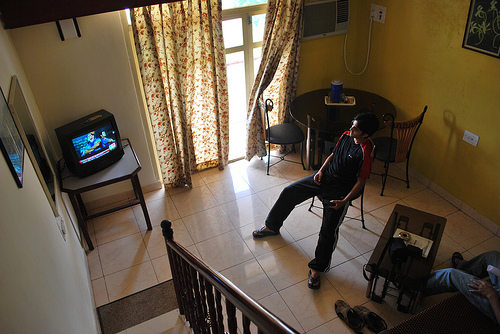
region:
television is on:
[49, 103, 140, 185]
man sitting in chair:
[247, 97, 386, 303]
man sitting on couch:
[403, 215, 498, 327]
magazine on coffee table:
[391, 215, 438, 262]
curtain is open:
[221, 0, 308, 167]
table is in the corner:
[278, 65, 421, 182]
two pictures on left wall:
[0, 52, 67, 245]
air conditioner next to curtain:
[300, 0, 401, 82]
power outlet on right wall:
[452, 115, 492, 160]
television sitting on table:
[50, 96, 170, 253]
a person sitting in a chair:
[240, 78, 425, 278]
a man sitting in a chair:
[257, 75, 407, 292]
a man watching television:
[19, 60, 436, 264]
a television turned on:
[54, 80, 171, 220]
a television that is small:
[39, 74, 153, 185]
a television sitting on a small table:
[50, 85, 182, 264]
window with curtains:
[118, 7, 400, 182]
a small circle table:
[232, 47, 444, 188]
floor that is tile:
[157, 188, 312, 316]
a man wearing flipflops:
[228, 60, 419, 274]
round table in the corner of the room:
[283, 79, 404, 176]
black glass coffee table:
[364, 200, 450, 311]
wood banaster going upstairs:
[150, 204, 298, 332]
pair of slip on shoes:
[333, 299, 385, 332]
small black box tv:
[56, 105, 128, 178]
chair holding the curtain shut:
[237, 62, 309, 177]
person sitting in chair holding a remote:
[247, 108, 382, 287]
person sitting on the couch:
[417, 235, 497, 326]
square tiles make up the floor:
[48, 120, 495, 328]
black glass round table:
[286, 76, 416, 145]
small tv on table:
[49, 115, 134, 166]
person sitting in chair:
[255, 120, 385, 290]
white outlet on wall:
[451, 127, 481, 154]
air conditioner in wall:
[298, 0, 365, 58]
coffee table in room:
[376, 200, 431, 299]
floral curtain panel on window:
[150, 27, 232, 174]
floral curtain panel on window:
[264, 7, 306, 164]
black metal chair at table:
[251, 102, 305, 164]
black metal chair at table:
[378, 106, 428, 188]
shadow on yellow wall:
[437, 112, 483, 197]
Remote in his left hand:
[303, 172, 352, 214]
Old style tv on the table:
[36, 97, 158, 191]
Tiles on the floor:
[126, 169, 476, 319]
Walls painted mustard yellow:
[291, 7, 496, 227]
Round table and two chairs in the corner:
[239, 52, 446, 203]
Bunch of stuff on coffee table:
[362, 211, 442, 316]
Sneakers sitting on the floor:
[314, 280, 395, 332]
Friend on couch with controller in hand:
[350, 214, 497, 329]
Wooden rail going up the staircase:
[133, 208, 288, 332]